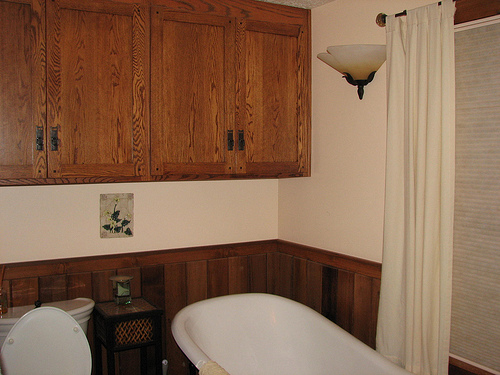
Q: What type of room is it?
A: It is a bathroom.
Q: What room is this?
A: It is a bathroom.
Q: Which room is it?
A: It is a bathroom.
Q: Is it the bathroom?
A: Yes, it is the bathroom.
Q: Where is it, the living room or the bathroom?
A: It is the bathroom.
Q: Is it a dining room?
A: No, it is a bathroom.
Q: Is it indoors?
A: Yes, it is indoors.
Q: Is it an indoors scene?
A: Yes, it is indoors.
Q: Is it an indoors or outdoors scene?
A: It is indoors.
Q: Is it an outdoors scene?
A: No, it is indoors.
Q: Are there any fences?
A: No, there are no fences.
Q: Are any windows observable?
A: Yes, there is a window.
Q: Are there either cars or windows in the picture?
A: Yes, there is a window.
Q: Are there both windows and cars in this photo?
A: No, there is a window but no cars.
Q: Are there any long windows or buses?
A: Yes, there is a long window.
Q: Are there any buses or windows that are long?
A: Yes, the window is long.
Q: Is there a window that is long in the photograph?
A: Yes, there is a long window.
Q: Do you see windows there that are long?
A: Yes, there is a long window.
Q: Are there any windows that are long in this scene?
A: Yes, there is a long window.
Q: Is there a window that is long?
A: Yes, there is a window that is long.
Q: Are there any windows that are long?
A: Yes, there is a window that is long.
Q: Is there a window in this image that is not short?
A: Yes, there is a long window.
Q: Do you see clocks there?
A: No, there are no clocks.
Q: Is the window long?
A: Yes, the window is long.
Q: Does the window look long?
A: Yes, the window is long.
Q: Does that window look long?
A: Yes, the window is long.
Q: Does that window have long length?
A: Yes, the window is long.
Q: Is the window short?
A: No, the window is long.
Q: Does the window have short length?
A: No, the window is long.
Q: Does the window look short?
A: No, the window is long.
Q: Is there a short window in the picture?
A: No, there is a window but it is long.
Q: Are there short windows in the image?
A: No, there is a window but it is long.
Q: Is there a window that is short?
A: No, there is a window but it is long.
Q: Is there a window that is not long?
A: No, there is a window but it is long.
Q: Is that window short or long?
A: The window is long.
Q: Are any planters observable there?
A: No, there are no planters.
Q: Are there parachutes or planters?
A: No, there are no planters or parachutes.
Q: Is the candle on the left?
A: Yes, the candle is on the left of the image.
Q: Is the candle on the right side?
A: No, the candle is on the left of the image.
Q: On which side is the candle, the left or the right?
A: The candle is on the left of the image.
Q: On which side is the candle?
A: The candle is on the left of the image.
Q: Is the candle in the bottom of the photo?
A: Yes, the candle is in the bottom of the image.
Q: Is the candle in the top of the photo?
A: No, the candle is in the bottom of the image.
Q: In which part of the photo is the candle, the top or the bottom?
A: The candle is in the bottom of the image.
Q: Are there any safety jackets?
A: No, there are no safety jackets.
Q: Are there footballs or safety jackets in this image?
A: No, there are no safety jackets or footballs.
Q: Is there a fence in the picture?
A: No, there are no fences.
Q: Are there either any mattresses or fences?
A: No, there are no fences or mattresses.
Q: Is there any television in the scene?
A: No, there are no televisions.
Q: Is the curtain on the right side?
A: Yes, the curtain is on the right of the image.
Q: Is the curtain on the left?
A: No, the curtain is on the right of the image.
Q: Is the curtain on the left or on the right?
A: The curtain is on the right of the image.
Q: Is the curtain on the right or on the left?
A: The curtain is on the right of the image.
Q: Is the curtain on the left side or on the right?
A: The curtain is on the right of the image.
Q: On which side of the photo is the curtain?
A: The curtain is on the right of the image.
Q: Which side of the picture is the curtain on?
A: The curtain is on the right of the image.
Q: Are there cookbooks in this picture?
A: No, there are no cookbooks.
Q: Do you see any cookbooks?
A: No, there are no cookbooks.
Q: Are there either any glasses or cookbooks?
A: No, there are no cookbooks or glasses.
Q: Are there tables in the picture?
A: Yes, there is a table.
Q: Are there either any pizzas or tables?
A: Yes, there is a table.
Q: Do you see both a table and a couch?
A: No, there is a table but no couches.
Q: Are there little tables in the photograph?
A: Yes, there is a little table.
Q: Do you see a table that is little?
A: Yes, there is a table that is little.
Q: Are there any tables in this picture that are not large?
A: Yes, there is a little table.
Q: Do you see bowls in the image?
A: No, there are no bowls.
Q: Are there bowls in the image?
A: No, there are no bowls.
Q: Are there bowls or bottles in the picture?
A: No, there are no bowls or bottles.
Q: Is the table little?
A: Yes, the table is little.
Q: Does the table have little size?
A: Yes, the table is little.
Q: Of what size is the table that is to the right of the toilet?
A: The table is little.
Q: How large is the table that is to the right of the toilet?
A: The table is little.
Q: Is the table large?
A: No, the table is little.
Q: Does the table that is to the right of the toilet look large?
A: No, the table is little.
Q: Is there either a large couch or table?
A: No, there is a table but it is little.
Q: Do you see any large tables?
A: No, there is a table but it is little.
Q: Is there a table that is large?
A: No, there is a table but it is little.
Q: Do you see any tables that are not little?
A: No, there is a table but it is little.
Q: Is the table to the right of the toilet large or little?
A: The table is little.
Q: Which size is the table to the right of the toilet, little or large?
A: The table is little.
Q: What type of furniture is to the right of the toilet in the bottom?
A: The piece of furniture is a table.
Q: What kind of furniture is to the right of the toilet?
A: The piece of furniture is a table.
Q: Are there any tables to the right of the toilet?
A: Yes, there is a table to the right of the toilet.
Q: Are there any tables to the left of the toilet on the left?
A: No, the table is to the right of the toilet.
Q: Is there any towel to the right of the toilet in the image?
A: No, there is a table to the right of the toilet.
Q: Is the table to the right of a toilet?
A: Yes, the table is to the right of a toilet.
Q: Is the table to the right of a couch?
A: No, the table is to the right of a toilet.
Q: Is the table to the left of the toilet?
A: No, the table is to the right of the toilet.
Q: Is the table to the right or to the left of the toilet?
A: The table is to the right of the toilet.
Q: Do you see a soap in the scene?
A: No, there are no soaps.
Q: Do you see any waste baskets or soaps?
A: No, there are no soaps or waste baskets.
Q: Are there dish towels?
A: No, there are no dish towels.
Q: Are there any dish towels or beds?
A: No, there are no dish towels or beds.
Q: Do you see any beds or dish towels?
A: No, there are no dish towels or beds.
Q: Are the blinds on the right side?
A: Yes, the blinds are on the right of the image.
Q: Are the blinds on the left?
A: No, the blinds are on the right of the image.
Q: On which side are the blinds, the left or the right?
A: The blinds are on the right of the image.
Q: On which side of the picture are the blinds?
A: The blinds are on the right of the image.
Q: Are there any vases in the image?
A: No, there are no vases.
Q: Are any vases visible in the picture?
A: No, there are no vases.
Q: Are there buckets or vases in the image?
A: No, there are no vases or buckets.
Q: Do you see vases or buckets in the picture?
A: No, there are no vases or buckets.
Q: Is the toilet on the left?
A: Yes, the toilet is on the left of the image.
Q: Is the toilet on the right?
A: No, the toilet is on the left of the image.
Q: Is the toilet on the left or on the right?
A: The toilet is on the left of the image.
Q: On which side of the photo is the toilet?
A: The toilet is on the left of the image.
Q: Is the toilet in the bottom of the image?
A: Yes, the toilet is in the bottom of the image.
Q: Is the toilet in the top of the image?
A: No, the toilet is in the bottom of the image.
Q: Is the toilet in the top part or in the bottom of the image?
A: The toilet is in the bottom of the image.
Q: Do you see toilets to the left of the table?
A: Yes, there is a toilet to the left of the table.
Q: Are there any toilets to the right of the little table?
A: No, the toilet is to the left of the table.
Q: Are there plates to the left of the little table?
A: No, there is a toilet to the left of the table.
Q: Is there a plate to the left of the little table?
A: No, there is a toilet to the left of the table.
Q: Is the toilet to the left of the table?
A: Yes, the toilet is to the left of the table.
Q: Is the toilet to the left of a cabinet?
A: No, the toilet is to the left of the table.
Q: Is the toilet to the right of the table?
A: No, the toilet is to the left of the table.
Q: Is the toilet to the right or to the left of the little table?
A: The toilet is to the left of the table.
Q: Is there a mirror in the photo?
A: No, there are no mirrors.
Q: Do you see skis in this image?
A: No, there are no skis.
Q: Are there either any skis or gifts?
A: No, there are no skis or gifts.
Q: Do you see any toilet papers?
A: No, there are no toilet papers.